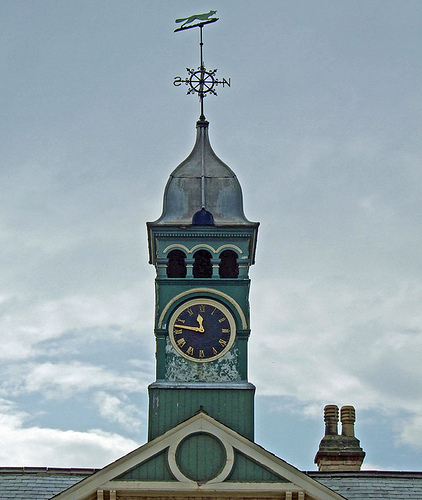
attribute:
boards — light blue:
[174, 431, 224, 475]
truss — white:
[16, 393, 421, 498]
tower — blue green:
[137, 106, 265, 426]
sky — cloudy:
[284, 93, 394, 324]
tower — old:
[135, 3, 266, 448]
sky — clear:
[39, 403, 91, 426]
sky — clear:
[269, 419, 310, 446]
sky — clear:
[372, 431, 404, 463]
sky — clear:
[89, 345, 136, 371]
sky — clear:
[264, 419, 297, 440]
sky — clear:
[19, 393, 42, 409]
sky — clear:
[93, 345, 131, 368]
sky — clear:
[25, 32, 118, 105]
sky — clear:
[264, 417, 313, 447]